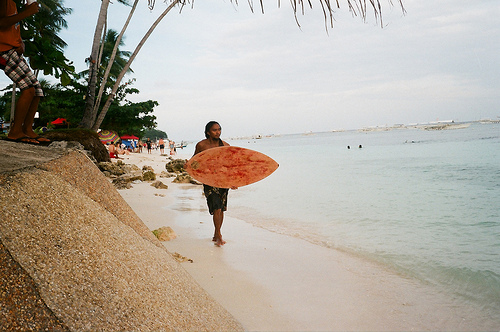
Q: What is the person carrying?
A: Carrying a surfboard.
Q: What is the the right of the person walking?
A: A body of water.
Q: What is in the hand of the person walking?
A: A surfboard.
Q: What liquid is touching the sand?
A: Water.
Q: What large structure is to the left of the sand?
A: A rock.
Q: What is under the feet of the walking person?
A: Sand.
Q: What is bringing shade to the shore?
A: The trees.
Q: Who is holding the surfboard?
A: A man.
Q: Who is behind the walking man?
A: A group of people.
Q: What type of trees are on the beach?
A: Palm trees.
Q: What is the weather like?
A: Partly cloudy.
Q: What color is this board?
A: Orange.